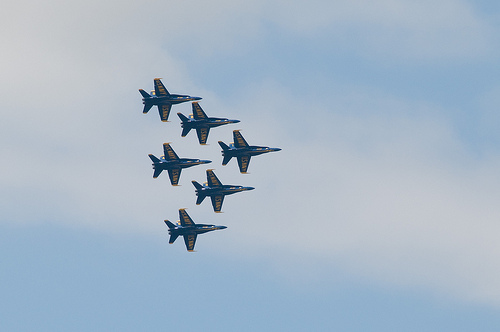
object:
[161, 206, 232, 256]
flying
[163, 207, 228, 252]
jet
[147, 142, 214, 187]
jet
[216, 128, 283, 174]
jet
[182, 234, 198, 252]
wings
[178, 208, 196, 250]
"us navy"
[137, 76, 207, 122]
plane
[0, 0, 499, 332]
sky